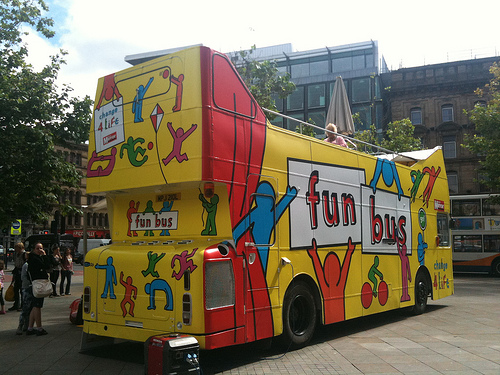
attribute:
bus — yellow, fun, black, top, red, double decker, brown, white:
[73, 43, 463, 373]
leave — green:
[15, 88, 83, 112]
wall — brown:
[407, 47, 471, 120]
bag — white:
[17, 257, 80, 298]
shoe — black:
[15, 321, 53, 349]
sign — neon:
[5, 213, 33, 244]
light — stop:
[68, 194, 103, 256]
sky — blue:
[155, 18, 179, 30]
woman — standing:
[17, 240, 66, 303]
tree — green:
[29, 100, 71, 128]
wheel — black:
[244, 280, 320, 371]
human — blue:
[109, 59, 172, 145]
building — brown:
[407, 74, 451, 111]